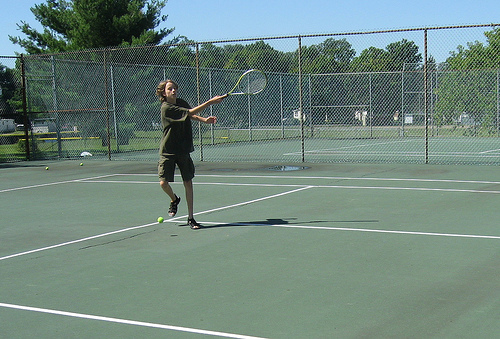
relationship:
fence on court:
[10, 20, 499, 165] [87, 134, 399, 333]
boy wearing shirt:
[153, 80, 223, 230] [152, 95, 199, 158]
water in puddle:
[273, 157, 313, 173] [275, 160, 312, 177]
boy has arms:
[153, 80, 223, 230] [187, 89, 227, 126]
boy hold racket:
[153, 80, 223, 230] [217, 65, 272, 102]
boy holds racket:
[153, 80, 223, 230] [202, 67, 271, 109]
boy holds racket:
[142, 61, 218, 229] [198, 58, 277, 105]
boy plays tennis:
[153, 80, 223, 230] [105, 41, 305, 242]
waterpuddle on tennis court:
[268, 162, 305, 173] [260, 157, 320, 179]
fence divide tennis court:
[10, 20, 499, 165] [10, 116, 498, 336]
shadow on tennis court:
[194, 204, 379, 231] [6, 161, 499, 334]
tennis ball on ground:
[80, 163, 84, 166] [13, 141, 130, 201]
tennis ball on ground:
[40, 161, 53, 171] [13, 141, 130, 201]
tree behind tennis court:
[9, 0, 189, 155] [6, 161, 499, 334]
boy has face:
[153, 80, 223, 230] [155, 82, 182, 101]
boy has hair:
[153, 80, 223, 230] [156, 76, 178, 99]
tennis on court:
[157, 217, 164, 224] [0, 149, 499, 337]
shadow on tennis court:
[177, 217, 378, 229] [67, 123, 428, 325]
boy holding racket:
[153, 80, 223, 230] [218, 64, 266, 103]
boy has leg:
[153, 80, 223, 230] [178, 158, 199, 227]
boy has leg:
[153, 80, 223, 230] [158, 155, 198, 227]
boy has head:
[153, 80, 223, 230] [152, 74, 179, 102]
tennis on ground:
[157, 217, 164, 224] [1, 125, 497, 337]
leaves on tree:
[36, 1, 167, 42] [9, 0, 189, 155]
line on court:
[300, 182, 499, 197] [0, 149, 499, 337]